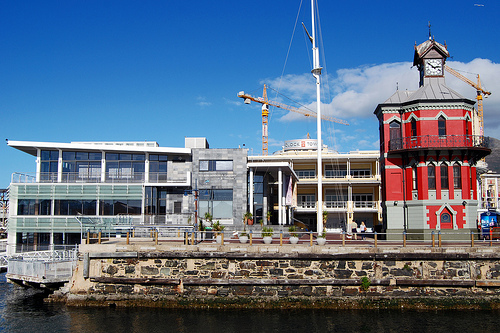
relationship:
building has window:
[377, 31, 481, 234] [425, 161, 436, 192]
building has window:
[377, 31, 481, 234] [438, 161, 449, 190]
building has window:
[377, 31, 481, 234] [451, 162, 462, 189]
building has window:
[189, 150, 246, 231] [437, 117, 447, 144]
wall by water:
[63, 243, 500, 309] [8, 305, 482, 330]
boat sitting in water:
[17, 246, 64, 286] [4, 282, 73, 324]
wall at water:
[117, 221, 385, 322] [117, 294, 364, 326]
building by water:
[372, 20, 493, 242] [61, 296, 494, 331]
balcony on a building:
[400, 131, 494, 153] [381, 25, 491, 233]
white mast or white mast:
[301, 0, 340, 250] [309, 0, 326, 238]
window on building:
[406, 109, 426, 148] [1, 120, 245, 300]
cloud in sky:
[263, 69, 372, 124] [100, 33, 324, 147]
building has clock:
[372, 20, 493, 242] [380, 26, 482, 83]